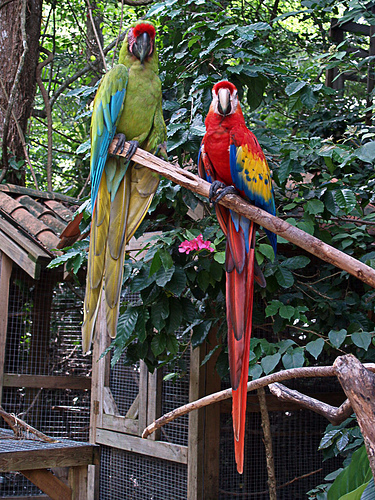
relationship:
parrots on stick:
[90, 12, 277, 478] [97, 131, 373, 314]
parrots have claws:
[90, 12, 277, 478] [104, 134, 240, 207]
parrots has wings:
[190, 66, 277, 478] [211, 125, 284, 250]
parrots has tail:
[190, 66, 277, 478] [204, 225, 262, 483]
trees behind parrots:
[0, 1, 375, 379] [90, 12, 277, 478]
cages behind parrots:
[3, 184, 363, 496] [90, 12, 277, 478]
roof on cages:
[2, 188, 147, 284] [3, 184, 363, 496]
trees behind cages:
[0, 1, 375, 379] [3, 184, 363, 496]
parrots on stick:
[190, 66, 277, 478] [97, 131, 373, 314]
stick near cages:
[97, 131, 373, 314] [3, 184, 363, 496]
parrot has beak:
[62, 12, 165, 381] [130, 32, 158, 68]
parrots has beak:
[190, 66, 277, 478] [212, 88, 236, 122]